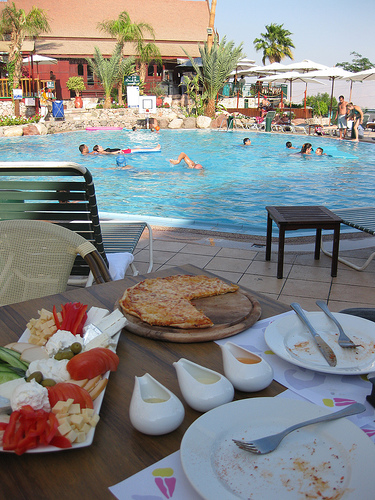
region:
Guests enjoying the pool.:
[78, 120, 334, 180]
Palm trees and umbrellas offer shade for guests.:
[229, 15, 366, 135]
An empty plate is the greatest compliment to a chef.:
[174, 392, 365, 497]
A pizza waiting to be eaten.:
[120, 259, 240, 334]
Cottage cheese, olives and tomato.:
[55, 336, 86, 380]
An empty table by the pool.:
[262, 169, 345, 280]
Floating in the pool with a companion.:
[75, 140, 165, 160]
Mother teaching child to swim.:
[296, 136, 332, 165]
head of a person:
[75, 135, 90, 154]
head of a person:
[92, 145, 104, 151]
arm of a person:
[169, 150, 198, 168]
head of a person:
[239, 130, 252, 146]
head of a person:
[280, 133, 296, 146]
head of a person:
[296, 143, 315, 154]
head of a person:
[315, 143, 325, 155]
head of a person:
[333, 83, 346, 103]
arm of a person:
[329, 103, 340, 123]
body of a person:
[336, 100, 347, 112]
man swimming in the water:
[160, 149, 206, 176]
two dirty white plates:
[188, 306, 373, 498]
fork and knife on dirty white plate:
[289, 296, 360, 365]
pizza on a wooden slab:
[116, 274, 260, 342]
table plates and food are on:
[1, 264, 370, 498]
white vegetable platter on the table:
[1, 300, 127, 446]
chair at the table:
[0, 215, 123, 298]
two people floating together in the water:
[81, 134, 163, 157]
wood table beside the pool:
[265, 203, 345, 276]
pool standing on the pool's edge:
[331, 93, 369, 140]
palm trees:
[87, 12, 160, 108]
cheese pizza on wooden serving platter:
[114, 274, 261, 341]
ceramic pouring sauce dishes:
[127, 340, 272, 434]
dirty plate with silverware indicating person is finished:
[265, 299, 373, 375]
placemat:
[109, 389, 373, 499]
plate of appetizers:
[0, 300, 128, 453]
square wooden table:
[266, 204, 342, 276]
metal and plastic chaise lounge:
[1, 167, 152, 282]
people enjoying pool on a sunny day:
[0, 127, 372, 237]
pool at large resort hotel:
[0, 0, 372, 499]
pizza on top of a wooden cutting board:
[117, 271, 239, 336]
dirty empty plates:
[178, 295, 374, 497]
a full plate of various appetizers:
[3, 300, 130, 458]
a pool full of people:
[1, 118, 372, 241]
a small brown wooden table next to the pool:
[259, 200, 343, 278]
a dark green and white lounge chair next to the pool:
[0, 149, 156, 290]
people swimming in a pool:
[78, 129, 331, 184]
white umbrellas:
[232, 56, 373, 98]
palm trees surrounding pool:
[1, 3, 298, 121]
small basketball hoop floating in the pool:
[136, 91, 166, 132]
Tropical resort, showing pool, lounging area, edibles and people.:
[2, 1, 371, 499]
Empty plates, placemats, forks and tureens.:
[137, 313, 374, 495]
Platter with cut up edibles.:
[8, 306, 118, 456]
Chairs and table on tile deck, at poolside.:
[4, 165, 373, 300]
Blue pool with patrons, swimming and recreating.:
[24, 131, 363, 202]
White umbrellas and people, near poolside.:
[232, 66, 370, 138]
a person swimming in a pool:
[169, 148, 219, 183]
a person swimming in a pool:
[72, 139, 95, 159]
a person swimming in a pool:
[93, 140, 168, 161]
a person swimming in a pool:
[233, 133, 265, 156]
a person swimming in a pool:
[278, 135, 298, 152]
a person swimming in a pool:
[295, 138, 315, 160]